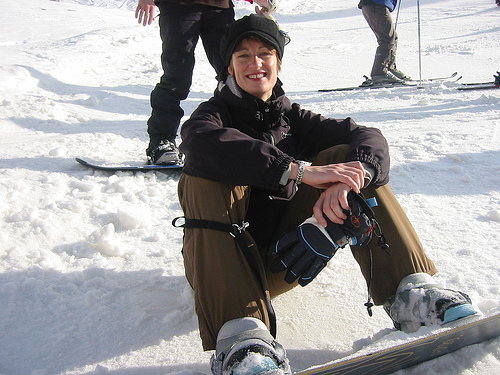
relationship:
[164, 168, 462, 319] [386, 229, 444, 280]
pants has wrinkles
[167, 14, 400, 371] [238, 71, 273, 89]
woman has mouth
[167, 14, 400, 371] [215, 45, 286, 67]
woman has eyes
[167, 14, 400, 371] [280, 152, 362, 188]
woman has hand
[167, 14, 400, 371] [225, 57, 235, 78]
woman has ear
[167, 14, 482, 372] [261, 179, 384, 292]
woman holding gloves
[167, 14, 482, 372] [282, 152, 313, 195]
woman wearing watch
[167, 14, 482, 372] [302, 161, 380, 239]
woman holding wrist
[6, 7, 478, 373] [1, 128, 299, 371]
ground covered in snow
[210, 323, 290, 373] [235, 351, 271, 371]
foot has snow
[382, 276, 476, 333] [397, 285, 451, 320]
foot has snow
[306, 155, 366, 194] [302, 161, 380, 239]
hand holding wrist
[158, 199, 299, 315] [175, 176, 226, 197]
strap connected under knee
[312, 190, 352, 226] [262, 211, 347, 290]
fingers curled around glove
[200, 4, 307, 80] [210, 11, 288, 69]
hat on head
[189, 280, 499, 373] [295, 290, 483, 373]
feet on snowboard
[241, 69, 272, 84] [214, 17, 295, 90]
grin on face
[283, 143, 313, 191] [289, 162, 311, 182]
bracelet on wrist